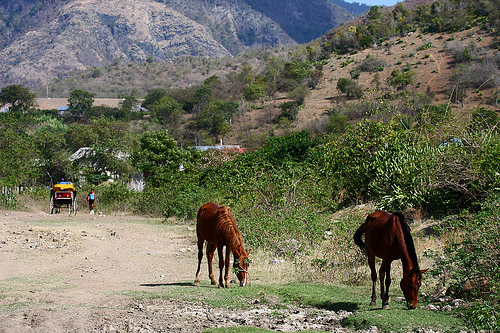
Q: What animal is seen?
A: Horse.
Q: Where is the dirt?
A: On ground.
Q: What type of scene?
A: Mountainside.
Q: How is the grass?
A: Short.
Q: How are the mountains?
A: Tall.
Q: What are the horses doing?
A: Eating.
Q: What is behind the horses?
A: Mountains.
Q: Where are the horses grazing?
A: On grass.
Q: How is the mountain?
A: Sparse foliage.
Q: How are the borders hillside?
A: Green vegetation.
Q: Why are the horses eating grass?
A: To fill stomach.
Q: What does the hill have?
A: Bunch of bushes.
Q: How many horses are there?
A: Two.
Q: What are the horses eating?
A: Grass.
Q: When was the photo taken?
A: Daytime.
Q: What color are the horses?
A: Brown.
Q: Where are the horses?
A: At the bottom of the hill.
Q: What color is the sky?
A: Blue.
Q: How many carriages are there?
A: One.